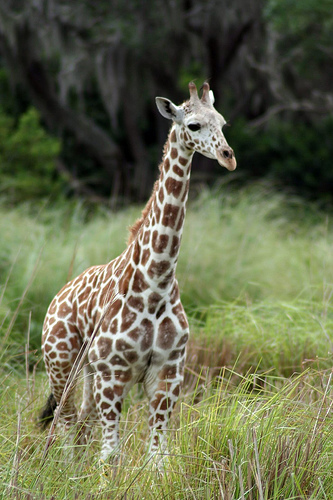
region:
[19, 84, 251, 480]
a giraffe standing in a field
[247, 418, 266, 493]
tall brown dried weeds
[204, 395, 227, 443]
tall green grass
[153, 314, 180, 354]
brown spots on fur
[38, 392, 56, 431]
black hair on a tail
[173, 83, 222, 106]
horns on a head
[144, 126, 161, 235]
a mane on a back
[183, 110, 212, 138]
a black eye on a head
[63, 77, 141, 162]
leafless trees in the background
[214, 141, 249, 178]
nostrils on a snout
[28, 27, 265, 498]
A giraffe standing in tall grass.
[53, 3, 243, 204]
Trees in the background behind a giraffe.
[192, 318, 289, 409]
Grass that is green and brown.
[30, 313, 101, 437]
A giraffe's tail and leg.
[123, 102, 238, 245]
A giraffe neck and mane.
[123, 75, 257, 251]
A small giraffe head on a long neck.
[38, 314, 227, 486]
The four legs of a giraffe.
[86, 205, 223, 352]
A giraffes brown spots.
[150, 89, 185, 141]
One of a giraffe's ears.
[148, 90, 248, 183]
The ear,eye,and nose of a giraffe.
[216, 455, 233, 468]
small green bud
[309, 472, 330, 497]
single blade of green grass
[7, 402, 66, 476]
several parched brown blade of grass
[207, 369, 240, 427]
yellow strand of grass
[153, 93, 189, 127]
long tan ears of giraffe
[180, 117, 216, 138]
large black eyes on giraffe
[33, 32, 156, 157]
ghostly tree in background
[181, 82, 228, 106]
two horns on giraffe's head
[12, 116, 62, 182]
large bright green trees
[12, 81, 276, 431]
large giraffe in tall grass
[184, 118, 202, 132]
a zebra's eye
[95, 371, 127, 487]
a zebra's leg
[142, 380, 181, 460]
a zebra's leg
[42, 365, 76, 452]
a zebra's leg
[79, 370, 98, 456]
a zebra's leg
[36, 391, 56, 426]
a zebra's tail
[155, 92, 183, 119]
a zebra's ear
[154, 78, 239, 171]
a zebra's head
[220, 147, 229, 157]
nostril of a zebra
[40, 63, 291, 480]
a zebra standing in the woods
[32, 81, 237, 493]
Giraffe in the wilderness.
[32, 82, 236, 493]
White and brown giraffe.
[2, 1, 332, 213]
Tree behind the giraffe.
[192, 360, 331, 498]
Tall brown and green grass.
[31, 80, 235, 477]
Giraffe standing on ground covered with tall grass.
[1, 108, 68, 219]
Green bush to the left side of the tree.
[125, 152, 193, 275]
Giraffe's neck.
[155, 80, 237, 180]
Head of a giraffe in the wilderness.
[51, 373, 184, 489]
Giraffe's four legs on the ground.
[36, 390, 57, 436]
End of the giraffe's tail.